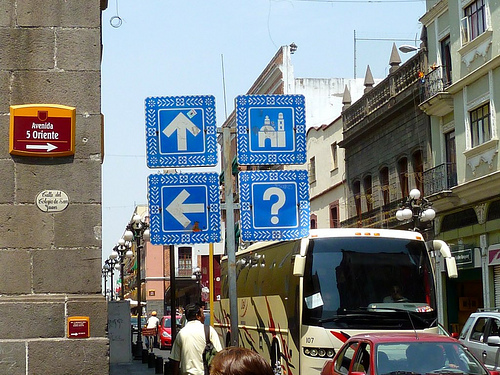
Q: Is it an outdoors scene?
A: Yes, it is outdoors.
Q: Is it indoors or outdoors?
A: It is outdoors.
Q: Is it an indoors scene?
A: No, it is outdoors.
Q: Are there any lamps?
A: Yes, there is a lamp.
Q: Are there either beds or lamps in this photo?
A: Yes, there is a lamp.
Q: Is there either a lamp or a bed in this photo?
A: Yes, there is a lamp.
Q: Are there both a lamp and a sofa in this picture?
A: No, there is a lamp but no sofas.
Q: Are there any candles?
A: No, there are no candles.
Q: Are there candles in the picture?
A: No, there are no candles.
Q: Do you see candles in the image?
A: No, there are no candles.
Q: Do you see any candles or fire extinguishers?
A: No, there are no candles or fire extinguishers.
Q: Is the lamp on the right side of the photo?
A: Yes, the lamp is on the right of the image.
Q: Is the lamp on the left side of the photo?
A: No, the lamp is on the right of the image.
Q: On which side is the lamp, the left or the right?
A: The lamp is on the right of the image.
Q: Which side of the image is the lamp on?
A: The lamp is on the right of the image.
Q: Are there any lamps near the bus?
A: Yes, there is a lamp near the bus.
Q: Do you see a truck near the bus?
A: No, there is a lamp near the bus.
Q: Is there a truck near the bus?
A: No, there is a lamp near the bus.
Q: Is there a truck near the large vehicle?
A: No, there is a lamp near the bus.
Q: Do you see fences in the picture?
A: No, there are no fences.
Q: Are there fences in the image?
A: No, there are no fences.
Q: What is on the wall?
A: The sign is on the wall.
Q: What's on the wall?
A: The sign is on the wall.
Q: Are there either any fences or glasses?
A: No, there are no fences or glasses.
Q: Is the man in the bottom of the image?
A: Yes, the man is in the bottom of the image.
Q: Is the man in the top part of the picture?
A: No, the man is in the bottom of the image.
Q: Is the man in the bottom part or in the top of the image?
A: The man is in the bottom of the image.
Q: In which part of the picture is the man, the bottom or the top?
A: The man is in the bottom of the image.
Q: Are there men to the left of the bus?
A: Yes, there is a man to the left of the bus.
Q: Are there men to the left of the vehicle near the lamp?
A: Yes, there is a man to the left of the bus.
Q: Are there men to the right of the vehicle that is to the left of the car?
A: No, the man is to the left of the bus.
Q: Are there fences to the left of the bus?
A: No, there is a man to the left of the bus.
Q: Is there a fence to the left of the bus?
A: No, there is a man to the left of the bus.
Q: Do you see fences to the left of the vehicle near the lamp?
A: No, there is a man to the left of the bus.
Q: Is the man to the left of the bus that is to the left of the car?
A: Yes, the man is to the left of the bus.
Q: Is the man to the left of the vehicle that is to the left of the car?
A: Yes, the man is to the left of the bus.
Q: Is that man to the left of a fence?
A: No, the man is to the left of the bus.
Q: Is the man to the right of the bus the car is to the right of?
A: No, the man is to the left of the bus.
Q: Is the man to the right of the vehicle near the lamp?
A: No, the man is to the left of the bus.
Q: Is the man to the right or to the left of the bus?
A: The man is to the left of the bus.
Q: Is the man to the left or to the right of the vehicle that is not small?
A: The man is to the left of the bus.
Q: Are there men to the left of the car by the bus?
A: Yes, there is a man to the left of the car.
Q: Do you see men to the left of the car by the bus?
A: Yes, there is a man to the left of the car.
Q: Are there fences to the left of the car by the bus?
A: No, there is a man to the left of the car.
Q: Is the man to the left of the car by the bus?
A: Yes, the man is to the left of the car.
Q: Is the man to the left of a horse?
A: No, the man is to the left of the car.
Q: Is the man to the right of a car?
A: No, the man is to the left of a car.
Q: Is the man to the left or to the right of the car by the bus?
A: The man is to the left of the car.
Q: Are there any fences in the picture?
A: No, there are no fences.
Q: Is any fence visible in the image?
A: No, there are no fences.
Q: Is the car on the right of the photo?
A: Yes, the car is on the right of the image.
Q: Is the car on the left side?
A: No, the car is on the right of the image.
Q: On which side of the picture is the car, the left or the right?
A: The car is on the right of the image.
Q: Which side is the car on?
A: The car is on the right of the image.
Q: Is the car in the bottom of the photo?
A: Yes, the car is in the bottom of the image.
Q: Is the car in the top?
A: No, the car is in the bottom of the image.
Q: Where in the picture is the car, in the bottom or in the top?
A: The car is in the bottom of the image.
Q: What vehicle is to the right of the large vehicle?
A: The vehicle is a car.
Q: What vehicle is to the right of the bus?
A: The vehicle is a car.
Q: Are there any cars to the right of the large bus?
A: Yes, there is a car to the right of the bus.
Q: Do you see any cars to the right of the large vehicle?
A: Yes, there is a car to the right of the bus.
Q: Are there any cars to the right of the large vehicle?
A: Yes, there is a car to the right of the bus.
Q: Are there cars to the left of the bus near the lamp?
A: No, the car is to the right of the bus.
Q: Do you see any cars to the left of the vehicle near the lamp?
A: No, the car is to the right of the bus.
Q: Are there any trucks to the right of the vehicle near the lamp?
A: No, there is a car to the right of the bus.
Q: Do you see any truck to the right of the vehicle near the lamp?
A: No, there is a car to the right of the bus.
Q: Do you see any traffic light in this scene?
A: No, there are no traffic lights.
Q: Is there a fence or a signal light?
A: No, there are no traffic lights or fences.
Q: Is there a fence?
A: No, there are no fences.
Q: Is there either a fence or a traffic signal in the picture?
A: No, there are no fences or traffic lights.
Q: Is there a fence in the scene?
A: No, there are no fences.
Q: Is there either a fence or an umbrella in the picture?
A: No, there are no fences or umbrellas.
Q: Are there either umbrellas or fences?
A: No, there are no fences or umbrellas.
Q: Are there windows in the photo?
A: Yes, there is a window.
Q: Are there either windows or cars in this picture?
A: Yes, there is a window.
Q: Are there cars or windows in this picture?
A: Yes, there is a window.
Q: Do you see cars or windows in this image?
A: Yes, there is a window.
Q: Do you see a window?
A: Yes, there is a window.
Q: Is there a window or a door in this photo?
A: Yes, there is a window.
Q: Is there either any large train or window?
A: Yes, there is a large window.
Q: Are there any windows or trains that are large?
A: Yes, the window is large.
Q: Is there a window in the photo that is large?
A: Yes, there is a large window.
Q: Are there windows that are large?
A: Yes, there is a window that is large.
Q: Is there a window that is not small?
A: Yes, there is a large window.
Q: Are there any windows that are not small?
A: Yes, there is a large window.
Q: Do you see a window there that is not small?
A: Yes, there is a large window.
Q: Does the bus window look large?
A: Yes, the window is large.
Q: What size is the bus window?
A: The window is large.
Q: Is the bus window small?
A: No, the window is large.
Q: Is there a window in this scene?
A: Yes, there are windows.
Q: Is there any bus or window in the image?
A: Yes, there are windows.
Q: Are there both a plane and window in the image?
A: No, there are windows but no airplanes.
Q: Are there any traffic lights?
A: No, there are no traffic lights.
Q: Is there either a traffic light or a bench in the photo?
A: No, there are no traffic lights or benches.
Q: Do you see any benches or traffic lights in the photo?
A: No, there are no traffic lights or benches.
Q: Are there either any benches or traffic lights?
A: No, there are no traffic lights or benches.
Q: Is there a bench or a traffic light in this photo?
A: No, there are no traffic lights or benches.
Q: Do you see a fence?
A: No, there are no fences.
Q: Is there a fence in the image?
A: No, there are no fences.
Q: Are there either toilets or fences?
A: No, there are no fences or toilets.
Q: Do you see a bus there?
A: Yes, there is a bus.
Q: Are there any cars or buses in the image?
A: Yes, there is a bus.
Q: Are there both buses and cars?
A: Yes, there are both a bus and a car.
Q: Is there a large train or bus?
A: Yes, there is a large bus.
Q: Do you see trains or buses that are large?
A: Yes, the bus is large.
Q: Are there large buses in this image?
A: Yes, there is a large bus.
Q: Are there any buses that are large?
A: Yes, there is a bus that is large.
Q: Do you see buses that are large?
A: Yes, there is a bus that is large.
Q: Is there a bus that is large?
A: Yes, there is a bus that is large.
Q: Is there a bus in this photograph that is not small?
A: Yes, there is a large bus.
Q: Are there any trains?
A: No, there are no trains.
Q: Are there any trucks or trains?
A: No, there are no trains or trucks.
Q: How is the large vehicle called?
A: The vehicle is a bus.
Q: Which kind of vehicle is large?
A: The vehicle is a bus.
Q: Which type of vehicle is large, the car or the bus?
A: The bus is large.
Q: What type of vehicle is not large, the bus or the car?
A: The car is not large.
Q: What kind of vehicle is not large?
A: The vehicle is a car.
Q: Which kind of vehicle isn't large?
A: The vehicle is a car.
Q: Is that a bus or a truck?
A: That is a bus.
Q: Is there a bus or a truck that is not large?
A: No, there is a bus but it is large.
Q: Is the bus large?
A: Yes, the bus is large.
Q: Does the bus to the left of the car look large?
A: Yes, the bus is large.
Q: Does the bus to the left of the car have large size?
A: Yes, the bus is large.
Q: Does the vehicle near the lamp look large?
A: Yes, the bus is large.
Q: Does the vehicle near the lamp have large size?
A: Yes, the bus is large.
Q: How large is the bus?
A: The bus is large.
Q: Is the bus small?
A: No, the bus is large.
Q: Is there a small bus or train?
A: No, there is a bus but it is large.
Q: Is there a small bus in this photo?
A: No, there is a bus but it is large.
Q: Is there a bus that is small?
A: No, there is a bus but it is large.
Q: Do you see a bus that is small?
A: No, there is a bus but it is large.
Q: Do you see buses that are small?
A: No, there is a bus but it is large.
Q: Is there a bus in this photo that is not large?
A: No, there is a bus but it is large.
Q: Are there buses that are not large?
A: No, there is a bus but it is large.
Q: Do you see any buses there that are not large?
A: No, there is a bus but it is large.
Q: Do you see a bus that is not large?
A: No, there is a bus but it is large.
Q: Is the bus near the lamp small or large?
A: The bus is large.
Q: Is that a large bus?
A: Yes, that is a large bus.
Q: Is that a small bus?
A: No, that is a large bus.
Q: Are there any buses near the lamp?
A: Yes, there is a bus near the lamp.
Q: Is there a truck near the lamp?
A: No, there is a bus near the lamp.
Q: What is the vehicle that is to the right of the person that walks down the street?
A: The vehicle is a bus.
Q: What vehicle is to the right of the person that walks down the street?
A: The vehicle is a bus.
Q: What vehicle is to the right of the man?
A: The vehicle is a bus.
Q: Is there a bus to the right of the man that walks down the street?
A: Yes, there is a bus to the right of the man.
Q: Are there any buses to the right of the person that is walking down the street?
A: Yes, there is a bus to the right of the man.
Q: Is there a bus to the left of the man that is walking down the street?
A: No, the bus is to the right of the man.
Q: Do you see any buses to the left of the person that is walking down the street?
A: No, the bus is to the right of the man.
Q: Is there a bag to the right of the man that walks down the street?
A: No, there is a bus to the right of the man.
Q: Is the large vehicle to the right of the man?
A: Yes, the bus is to the right of the man.